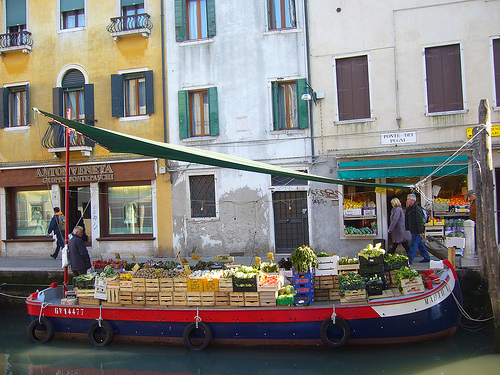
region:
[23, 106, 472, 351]
boat holds food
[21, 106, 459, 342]
boat floats in water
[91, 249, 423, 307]
food sits on boat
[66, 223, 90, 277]
human stands on boat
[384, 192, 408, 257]
woman walks along dock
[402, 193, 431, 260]
woman walks along dock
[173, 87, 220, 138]
window is on front of building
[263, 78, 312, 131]
window is on front of building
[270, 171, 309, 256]
door of building faces out onto dock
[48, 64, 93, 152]
window faces out onto the water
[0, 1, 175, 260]
a tall yellow building with black shutters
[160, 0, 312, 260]
a tall grey building with green shutters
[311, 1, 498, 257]
an off white building with brown shutters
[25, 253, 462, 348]
a river boat painted red, white and blue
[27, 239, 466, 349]
a boat full of fresh produce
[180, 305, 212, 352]
a black tire attached to a boat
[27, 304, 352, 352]
four black tires attached to a boat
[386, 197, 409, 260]
a blonde haired woman wearing a grey coat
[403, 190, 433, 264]
a grey haired man wearing a green jacket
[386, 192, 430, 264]
two people walking down the street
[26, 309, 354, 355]
four tires on the side of a boat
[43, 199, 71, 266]
man with a backpack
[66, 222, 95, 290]
man standing near the boat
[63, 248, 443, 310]
cartons of produce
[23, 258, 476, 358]
a boat full of produce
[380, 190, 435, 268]
a couple walking on the sidewalk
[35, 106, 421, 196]
green tarp over the boat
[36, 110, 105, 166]
small balcony under a window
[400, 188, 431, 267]
man pulling luggage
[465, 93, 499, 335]
pole tied to a tarp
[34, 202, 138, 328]
two person near road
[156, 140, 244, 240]
window on the building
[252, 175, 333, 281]
entrance of the home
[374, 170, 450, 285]
two people walking in road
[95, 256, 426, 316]
a mini store in the trolly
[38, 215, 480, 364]
a mini store in the boat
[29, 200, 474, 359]
a boat having all items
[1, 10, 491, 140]
a large group of buildings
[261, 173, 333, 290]
door of the building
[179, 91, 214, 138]
window on the building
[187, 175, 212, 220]
window on the building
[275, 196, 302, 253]
window on the building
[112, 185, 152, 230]
window on the building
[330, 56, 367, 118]
window on the building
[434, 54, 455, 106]
window on the building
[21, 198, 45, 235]
window on the building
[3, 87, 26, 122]
window on the building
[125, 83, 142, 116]
window on the building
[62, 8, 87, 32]
window on the building